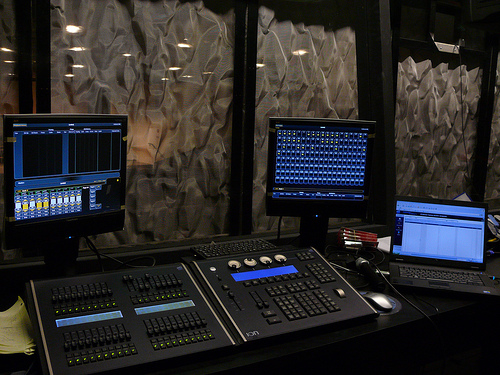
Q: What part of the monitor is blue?
A: The screen.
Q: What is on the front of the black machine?
A: Buttons.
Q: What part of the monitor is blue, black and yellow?
A: The screen.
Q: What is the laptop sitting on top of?
A: A desk.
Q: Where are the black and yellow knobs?
A: On the electronic board.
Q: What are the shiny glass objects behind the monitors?
A: Windows.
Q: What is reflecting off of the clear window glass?
A: Lights.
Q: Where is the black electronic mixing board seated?
A: On the desk.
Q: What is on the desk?
A: Black laptop computer.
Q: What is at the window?
A: Black wood jambs.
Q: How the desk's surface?
A: Black wooden.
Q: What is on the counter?
A: A sound mixer.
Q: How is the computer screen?
A: Showing different audio channels.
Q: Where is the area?
A: A music producers booth.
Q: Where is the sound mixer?
A: On a table.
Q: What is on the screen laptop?
A: File list.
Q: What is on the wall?
A: Sound proofing material.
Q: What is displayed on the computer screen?
A: Audio channels.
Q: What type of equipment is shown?
A: Music equipment.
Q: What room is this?
A: Sound studio.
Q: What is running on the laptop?
A: Program.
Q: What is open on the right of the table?
A: Laptop.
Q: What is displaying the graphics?
A: Monitor.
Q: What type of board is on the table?
A: Mixing board.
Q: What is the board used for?
A: Sound mixing.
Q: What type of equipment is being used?
A: Sound studio.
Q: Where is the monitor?
A: Control room.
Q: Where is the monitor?
A: Behind other monitor.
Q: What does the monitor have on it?
A: Icons.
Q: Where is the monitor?
A: Control room.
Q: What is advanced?
A: Sound board.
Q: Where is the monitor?
A: Near window.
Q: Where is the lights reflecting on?
A: Window.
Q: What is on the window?
A: Light reflecting.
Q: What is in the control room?
A: Monitor.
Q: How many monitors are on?
A: Three.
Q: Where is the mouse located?
A: To the right of the second console.